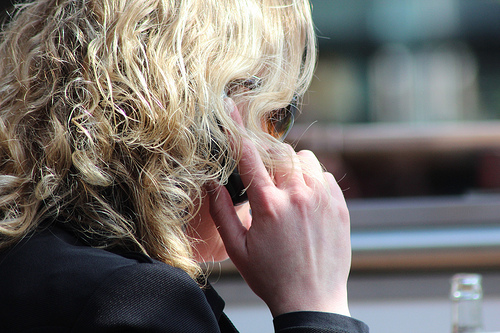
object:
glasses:
[249, 84, 299, 144]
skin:
[213, 99, 351, 316]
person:
[1, 0, 374, 333]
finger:
[219, 95, 280, 217]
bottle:
[448, 273, 484, 332]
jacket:
[0, 217, 374, 333]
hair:
[2, 0, 319, 283]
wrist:
[264, 275, 362, 329]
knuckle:
[292, 180, 314, 214]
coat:
[0, 216, 369, 333]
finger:
[206, 178, 246, 254]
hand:
[205, 95, 353, 301]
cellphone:
[200, 110, 253, 207]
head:
[4, 3, 317, 269]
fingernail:
[221, 96, 236, 112]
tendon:
[299, 212, 318, 289]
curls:
[66, 71, 208, 231]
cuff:
[272, 309, 368, 332]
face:
[185, 76, 284, 263]